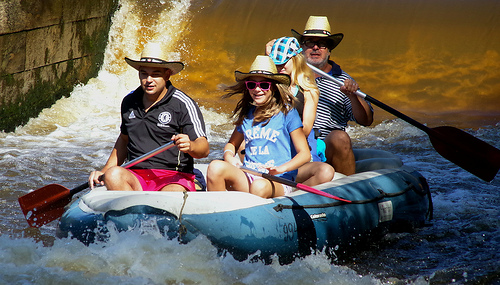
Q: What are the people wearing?
A: Hats.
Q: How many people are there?
A: Four.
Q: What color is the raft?
A: Blue and white.